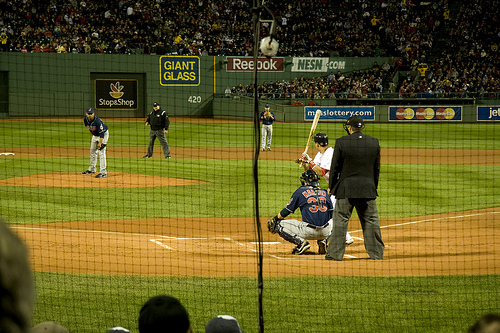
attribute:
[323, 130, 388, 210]
jacket — black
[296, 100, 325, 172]
bat — light brown, baseball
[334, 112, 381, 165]
umpire — home plate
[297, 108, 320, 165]
bat — wooden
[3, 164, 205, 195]
mound — red, clay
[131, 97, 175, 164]
umpire — standing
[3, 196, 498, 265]
line — white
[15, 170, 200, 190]
mound — dirt